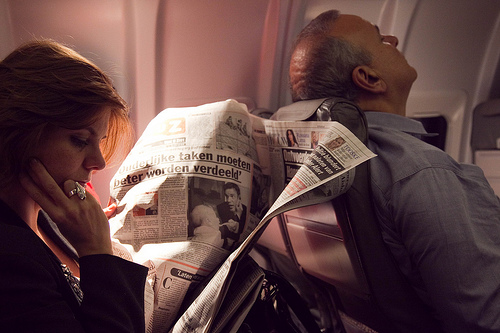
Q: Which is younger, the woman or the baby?
A: The baby is younger than the woman.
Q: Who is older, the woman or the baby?
A: The woman is older than the baby.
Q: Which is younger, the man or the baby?
A: The baby is younger than the man.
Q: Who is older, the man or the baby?
A: The man is older than the baby.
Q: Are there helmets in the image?
A: No, there are no helmets.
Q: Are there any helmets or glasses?
A: No, there are no helmets or glasses.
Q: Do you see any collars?
A: Yes, there is a collar.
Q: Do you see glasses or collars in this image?
A: Yes, there is a collar.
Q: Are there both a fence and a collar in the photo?
A: No, there is a collar but no fences.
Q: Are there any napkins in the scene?
A: No, there are no napkins.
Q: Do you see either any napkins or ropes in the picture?
A: No, there are no napkins or ropes.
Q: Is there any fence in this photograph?
A: No, there are no fences.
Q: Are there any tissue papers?
A: No, there are no tissue papers.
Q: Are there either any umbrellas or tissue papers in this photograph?
A: No, there are no tissue papers or umbrellas.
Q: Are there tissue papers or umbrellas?
A: No, there are no tissue papers or umbrellas.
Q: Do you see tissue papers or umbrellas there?
A: No, there are no tissue papers or umbrellas.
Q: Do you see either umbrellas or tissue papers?
A: No, there are no tissue papers or umbrellas.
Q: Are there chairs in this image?
A: Yes, there is a chair.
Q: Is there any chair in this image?
A: Yes, there is a chair.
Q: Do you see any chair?
A: Yes, there is a chair.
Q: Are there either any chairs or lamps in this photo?
A: Yes, there is a chair.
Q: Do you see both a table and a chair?
A: No, there is a chair but no tables.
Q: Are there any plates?
A: No, there are no plates.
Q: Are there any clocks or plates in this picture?
A: No, there are no plates or clocks.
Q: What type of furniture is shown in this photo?
A: The furniture is a chair.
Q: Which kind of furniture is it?
A: The piece of furniture is a chair.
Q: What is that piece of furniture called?
A: This is a chair.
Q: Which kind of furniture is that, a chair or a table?
A: This is a chair.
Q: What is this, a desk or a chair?
A: This is a chair.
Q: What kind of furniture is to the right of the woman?
A: The piece of furniture is a chair.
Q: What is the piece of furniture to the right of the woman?
A: The piece of furniture is a chair.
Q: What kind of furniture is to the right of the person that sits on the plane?
A: The piece of furniture is a chair.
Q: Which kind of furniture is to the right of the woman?
A: The piece of furniture is a chair.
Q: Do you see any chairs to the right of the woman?
A: Yes, there is a chair to the right of the woman.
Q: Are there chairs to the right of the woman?
A: Yes, there is a chair to the right of the woman.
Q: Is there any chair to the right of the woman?
A: Yes, there is a chair to the right of the woman.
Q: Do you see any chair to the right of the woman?
A: Yes, there is a chair to the right of the woman.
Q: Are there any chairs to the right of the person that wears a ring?
A: Yes, there is a chair to the right of the woman.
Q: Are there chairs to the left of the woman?
A: No, the chair is to the right of the woman.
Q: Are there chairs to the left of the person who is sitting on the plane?
A: No, the chair is to the right of the woman.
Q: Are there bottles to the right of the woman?
A: No, there is a chair to the right of the woman.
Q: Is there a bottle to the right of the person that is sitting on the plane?
A: No, there is a chair to the right of the woman.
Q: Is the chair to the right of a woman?
A: Yes, the chair is to the right of a woman.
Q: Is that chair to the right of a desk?
A: No, the chair is to the right of a woman.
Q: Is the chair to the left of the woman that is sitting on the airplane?
A: No, the chair is to the right of the woman.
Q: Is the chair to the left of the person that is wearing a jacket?
A: No, the chair is to the right of the woman.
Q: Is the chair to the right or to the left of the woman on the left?
A: The chair is to the right of the woman.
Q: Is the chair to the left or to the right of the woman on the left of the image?
A: The chair is to the right of the woman.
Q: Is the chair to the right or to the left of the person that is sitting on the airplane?
A: The chair is to the right of the woman.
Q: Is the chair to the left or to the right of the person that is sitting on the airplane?
A: The chair is to the right of the woman.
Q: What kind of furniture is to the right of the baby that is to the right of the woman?
A: The piece of furniture is a chair.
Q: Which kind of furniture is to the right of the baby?
A: The piece of furniture is a chair.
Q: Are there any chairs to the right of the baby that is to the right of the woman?
A: Yes, there is a chair to the right of the baby.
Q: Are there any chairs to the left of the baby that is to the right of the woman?
A: No, the chair is to the right of the baby.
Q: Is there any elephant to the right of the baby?
A: No, there is a chair to the right of the baby.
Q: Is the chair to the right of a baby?
A: Yes, the chair is to the right of a baby.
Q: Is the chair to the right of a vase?
A: No, the chair is to the right of a baby.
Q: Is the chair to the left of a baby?
A: No, the chair is to the right of a baby.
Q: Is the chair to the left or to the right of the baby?
A: The chair is to the right of the baby.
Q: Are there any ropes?
A: No, there are no ropes.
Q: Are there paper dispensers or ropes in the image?
A: No, there are no ropes or paper dispensers.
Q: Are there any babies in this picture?
A: Yes, there is a baby.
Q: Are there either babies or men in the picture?
A: Yes, there is a baby.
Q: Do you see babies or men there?
A: Yes, there is a baby.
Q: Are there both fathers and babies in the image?
A: No, there is a baby but no fathers.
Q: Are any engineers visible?
A: No, there are no engineers.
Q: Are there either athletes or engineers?
A: No, there are no engineers or athletes.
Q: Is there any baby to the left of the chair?
A: Yes, there is a baby to the left of the chair.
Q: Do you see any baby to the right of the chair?
A: No, the baby is to the left of the chair.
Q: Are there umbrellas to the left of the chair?
A: No, there is a baby to the left of the chair.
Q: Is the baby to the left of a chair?
A: Yes, the baby is to the left of a chair.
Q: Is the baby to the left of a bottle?
A: No, the baby is to the left of a chair.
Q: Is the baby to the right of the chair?
A: No, the baby is to the left of the chair.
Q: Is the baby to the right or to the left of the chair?
A: The baby is to the left of the chair.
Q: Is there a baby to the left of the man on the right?
A: Yes, there is a baby to the left of the man.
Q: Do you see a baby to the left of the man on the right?
A: Yes, there is a baby to the left of the man.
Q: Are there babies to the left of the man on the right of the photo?
A: Yes, there is a baby to the left of the man.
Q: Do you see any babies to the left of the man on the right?
A: Yes, there is a baby to the left of the man.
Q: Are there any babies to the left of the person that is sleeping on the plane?
A: Yes, there is a baby to the left of the man.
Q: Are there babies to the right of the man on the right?
A: No, the baby is to the left of the man.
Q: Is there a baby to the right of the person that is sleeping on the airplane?
A: No, the baby is to the left of the man.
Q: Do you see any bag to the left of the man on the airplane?
A: No, there is a baby to the left of the man.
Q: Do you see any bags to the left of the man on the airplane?
A: No, there is a baby to the left of the man.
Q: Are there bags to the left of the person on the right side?
A: No, there is a baby to the left of the man.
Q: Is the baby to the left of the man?
A: Yes, the baby is to the left of the man.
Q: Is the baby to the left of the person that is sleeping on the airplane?
A: Yes, the baby is to the left of the man.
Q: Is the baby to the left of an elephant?
A: No, the baby is to the left of the man.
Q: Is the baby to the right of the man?
A: No, the baby is to the left of the man.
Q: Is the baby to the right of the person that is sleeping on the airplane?
A: No, the baby is to the left of the man.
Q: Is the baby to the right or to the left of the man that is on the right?
A: The baby is to the left of the man.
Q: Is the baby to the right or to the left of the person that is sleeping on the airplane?
A: The baby is to the left of the man.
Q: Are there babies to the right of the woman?
A: Yes, there is a baby to the right of the woman.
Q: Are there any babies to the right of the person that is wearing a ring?
A: Yes, there is a baby to the right of the woman.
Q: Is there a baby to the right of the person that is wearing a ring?
A: Yes, there is a baby to the right of the woman.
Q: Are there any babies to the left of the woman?
A: No, the baby is to the right of the woman.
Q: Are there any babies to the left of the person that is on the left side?
A: No, the baby is to the right of the woman.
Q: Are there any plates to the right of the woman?
A: No, there is a baby to the right of the woman.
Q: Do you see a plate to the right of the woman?
A: No, there is a baby to the right of the woman.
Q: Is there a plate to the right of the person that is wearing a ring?
A: No, there is a baby to the right of the woman.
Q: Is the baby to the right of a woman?
A: Yes, the baby is to the right of a woman.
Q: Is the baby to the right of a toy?
A: No, the baby is to the right of a woman.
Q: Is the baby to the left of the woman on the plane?
A: No, the baby is to the right of the woman.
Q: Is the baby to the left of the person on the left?
A: No, the baby is to the right of the woman.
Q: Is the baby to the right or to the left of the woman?
A: The baby is to the right of the woman.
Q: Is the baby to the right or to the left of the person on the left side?
A: The baby is to the right of the woman.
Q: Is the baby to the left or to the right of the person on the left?
A: The baby is to the right of the woman.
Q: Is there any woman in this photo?
A: Yes, there is a woman.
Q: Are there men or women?
A: Yes, there is a woman.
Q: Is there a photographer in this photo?
A: No, there are no photographers.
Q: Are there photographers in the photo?
A: No, there are no photographers.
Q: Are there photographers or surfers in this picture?
A: No, there are no photographers or surfers.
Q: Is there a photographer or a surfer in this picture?
A: No, there are no photographers or surfers.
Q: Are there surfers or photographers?
A: No, there are no photographers or surfers.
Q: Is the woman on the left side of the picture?
A: Yes, the woman is on the left of the image.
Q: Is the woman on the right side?
A: No, the woman is on the left of the image.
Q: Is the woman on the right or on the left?
A: The woman is on the left of the image.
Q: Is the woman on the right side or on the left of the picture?
A: The woman is on the left of the image.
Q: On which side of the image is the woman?
A: The woman is on the left of the image.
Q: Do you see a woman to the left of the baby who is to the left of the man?
A: Yes, there is a woman to the left of the baby.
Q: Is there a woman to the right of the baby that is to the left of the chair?
A: No, the woman is to the left of the baby.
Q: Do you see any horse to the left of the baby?
A: No, there is a woman to the left of the baby.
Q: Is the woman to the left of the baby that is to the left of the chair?
A: Yes, the woman is to the left of the baby.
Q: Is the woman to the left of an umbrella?
A: No, the woman is to the left of the baby.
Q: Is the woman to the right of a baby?
A: No, the woman is to the left of a baby.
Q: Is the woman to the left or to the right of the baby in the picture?
A: The woman is to the left of the baby.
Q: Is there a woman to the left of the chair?
A: Yes, there is a woman to the left of the chair.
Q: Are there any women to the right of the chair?
A: No, the woman is to the left of the chair.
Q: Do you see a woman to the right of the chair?
A: No, the woman is to the left of the chair.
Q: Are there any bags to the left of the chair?
A: No, there is a woman to the left of the chair.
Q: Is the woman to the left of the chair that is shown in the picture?
A: Yes, the woman is to the left of the chair.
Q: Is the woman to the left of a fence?
A: No, the woman is to the left of the chair.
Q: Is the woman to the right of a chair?
A: No, the woman is to the left of a chair.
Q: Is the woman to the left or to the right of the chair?
A: The woman is to the left of the chair.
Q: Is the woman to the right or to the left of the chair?
A: The woman is to the left of the chair.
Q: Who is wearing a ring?
A: The woman is wearing a ring.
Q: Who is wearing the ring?
A: The woman is wearing a ring.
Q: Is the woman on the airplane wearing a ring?
A: Yes, the woman is wearing a ring.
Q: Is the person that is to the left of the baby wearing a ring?
A: Yes, the woman is wearing a ring.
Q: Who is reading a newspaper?
A: The woman is reading a newspaper.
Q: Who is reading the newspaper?
A: The woman is reading a newspaper.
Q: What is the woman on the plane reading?
A: The woman is reading a newspaper.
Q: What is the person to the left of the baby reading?
A: The woman is reading a newspaper.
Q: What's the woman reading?
A: The woman is reading a newspaper.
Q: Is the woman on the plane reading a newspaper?
A: Yes, the woman is reading a newspaper.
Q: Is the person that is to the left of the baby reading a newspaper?
A: Yes, the woman is reading a newspaper.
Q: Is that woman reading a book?
A: No, the woman is reading a newspaper.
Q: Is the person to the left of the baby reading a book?
A: No, the woman is reading a newspaper.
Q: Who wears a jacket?
A: The woman wears a jacket.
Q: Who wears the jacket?
A: The woman wears a jacket.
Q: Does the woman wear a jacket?
A: Yes, the woman wears a jacket.